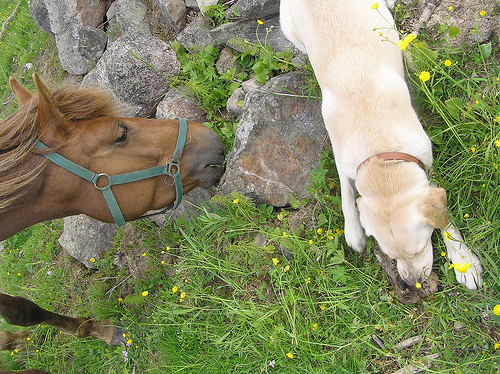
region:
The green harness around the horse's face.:
[30, 123, 200, 221]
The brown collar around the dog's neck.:
[356, 146, 426, 173]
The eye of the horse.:
[97, 117, 137, 148]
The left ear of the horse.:
[7, 78, 34, 106]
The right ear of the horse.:
[31, 70, 69, 133]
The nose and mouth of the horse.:
[201, 131, 231, 188]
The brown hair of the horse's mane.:
[11, 91, 107, 193]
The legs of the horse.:
[7, 264, 102, 371]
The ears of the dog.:
[350, 196, 455, 226]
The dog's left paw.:
[335, 209, 372, 264]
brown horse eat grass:
[5, 63, 287, 248]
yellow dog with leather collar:
[275, 1, 495, 327]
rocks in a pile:
[174, 38, 365, 318]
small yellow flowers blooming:
[239, 236, 360, 372]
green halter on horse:
[13, 92, 219, 269]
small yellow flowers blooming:
[365, 1, 497, 126]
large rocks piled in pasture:
[34, 3, 361, 108]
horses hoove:
[12, 274, 242, 371]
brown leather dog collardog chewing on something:
[327, 183, 480, 317]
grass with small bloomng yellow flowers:
[2, 8, 55, 57]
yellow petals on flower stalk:
[414, 56, 464, 96]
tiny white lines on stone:
[233, 162, 317, 207]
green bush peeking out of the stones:
[166, 26, 258, 99]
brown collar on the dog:
[337, 135, 444, 173]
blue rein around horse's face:
[28, 97, 218, 234]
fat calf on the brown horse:
[3, 287, 54, 331]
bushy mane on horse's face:
[41, 67, 151, 127]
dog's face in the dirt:
[357, 232, 456, 325]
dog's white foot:
[320, 224, 366, 269]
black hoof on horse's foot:
[104, 304, 146, 354]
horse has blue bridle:
[30, 122, 214, 203]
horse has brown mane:
[5, 82, 113, 220]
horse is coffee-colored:
[0, 103, 265, 228]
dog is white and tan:
[281, 0, 472, 308]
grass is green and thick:
[200, 237, 367, 369]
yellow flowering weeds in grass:
[224, 191, 342, 372]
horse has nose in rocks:
[48, 2, 326, 217]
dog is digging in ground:
[367, 237, 454, 333]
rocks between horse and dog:
[188, 65, 339, 215]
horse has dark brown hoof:
[97, 312, 156, 341]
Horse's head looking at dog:
[0, 73, 230, 243]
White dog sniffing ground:
[276, 0, 483, 290]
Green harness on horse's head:
[30, 113, 188, 225]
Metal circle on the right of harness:
[88, 167, 110, 192]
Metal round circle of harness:
[160, 158, 185, 174]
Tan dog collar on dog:
[333, 148, 426, 174]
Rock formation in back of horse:
[42, 2, 490, 283]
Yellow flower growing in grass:
[408, 60, 443, 95]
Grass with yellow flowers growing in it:
[0, 253, 490, 359]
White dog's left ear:
[409, 186, 449, 231]